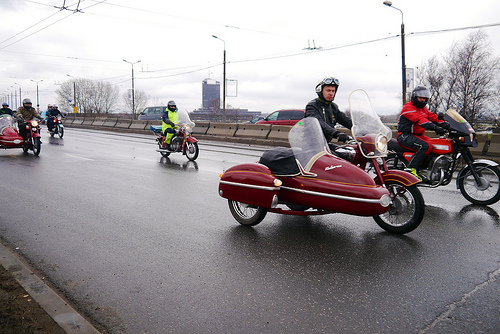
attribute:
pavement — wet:
[80, 110, 440, 315]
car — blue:
[138, 104, 167, 122]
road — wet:
[2, 128, 494, 324]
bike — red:
[407, 96, 492, 175]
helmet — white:
[315, 75, 339, 92]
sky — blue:
[258, 3, 358, 52]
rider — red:
[396, 81, 451, 142]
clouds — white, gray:
[2, 0, 499, 116]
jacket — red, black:
[398, 101, 443, 136]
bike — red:
[247, 141, 384, 214]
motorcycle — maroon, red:
[202, 103, 425, 257]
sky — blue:
[8, 0, 489, 118]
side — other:
[87, 106, 498, 166]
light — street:
[378, 0, 409, 24]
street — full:
[4, 107, 495, 327]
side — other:
[68, 105, 496, 163]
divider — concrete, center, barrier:
[60, 110, 497, 157]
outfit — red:
[397, 104, 443, 154]